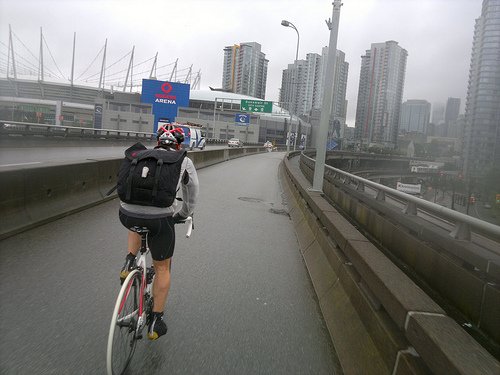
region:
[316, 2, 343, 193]
grey metal lamp post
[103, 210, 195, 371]
white and red mountain bike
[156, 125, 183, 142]
red and white bike helmet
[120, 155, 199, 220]
grey cotton sweat shirt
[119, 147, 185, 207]
black back pack on man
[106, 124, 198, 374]
man riding on bike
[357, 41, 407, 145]
grey concrete sky scraper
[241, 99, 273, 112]
green and white street sign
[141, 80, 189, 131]
arena sign by road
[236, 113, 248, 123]
blue and white street sign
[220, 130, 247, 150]
A silver car on the highway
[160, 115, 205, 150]
A blue/white van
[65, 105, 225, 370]
A man riding a bike on the highway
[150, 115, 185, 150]
A black/red/white bike helmet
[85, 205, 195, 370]
A red/white bike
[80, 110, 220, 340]
A man with a black backpack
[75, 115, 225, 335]
A man wearing a grey shirt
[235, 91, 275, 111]
A green road sign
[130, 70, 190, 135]
A sign for 'ROGERS ARENA'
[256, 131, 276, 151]
A white car in the distance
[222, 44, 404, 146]
Tall City Company Buildings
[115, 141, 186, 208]
Black double strap backpack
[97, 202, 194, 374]
White and Red Lightweight Bicycle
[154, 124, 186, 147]
Black, Red, and White Bicycle Helmet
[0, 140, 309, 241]
Concete Barrier Between roads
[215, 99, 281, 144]
Highway Express Signs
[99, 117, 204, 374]
Man Riding A Lightweight Bicycle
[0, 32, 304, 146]
Rogers Sports Arena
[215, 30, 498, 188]
Downtown Tall Skyscapers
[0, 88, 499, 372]
Highway and bicycle path to the city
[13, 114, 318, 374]
man biking down bikepath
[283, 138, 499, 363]
railings along bike path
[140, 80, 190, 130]
blue billboard with red and white lettering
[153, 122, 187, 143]
red, white, and black helmet of bicyclist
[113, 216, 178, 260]
black shorts of bicyclist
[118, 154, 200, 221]
gray shirt of bicyclist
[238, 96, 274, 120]
green and white street sign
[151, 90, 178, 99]
red lettering on blue sign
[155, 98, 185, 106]
white lettering on blue sign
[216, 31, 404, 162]
tall buildings in the background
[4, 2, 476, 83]
gray clouds in sky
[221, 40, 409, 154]
line of sky scrapers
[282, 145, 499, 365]
concrete barrier with flat top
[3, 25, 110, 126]
poles on circular roof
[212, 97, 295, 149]
green sign over road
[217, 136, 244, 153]
back of car on street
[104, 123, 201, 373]
back of man on bike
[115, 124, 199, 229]
black bag on back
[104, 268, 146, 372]
white wheel of bike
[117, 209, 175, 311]
black shorts on legs